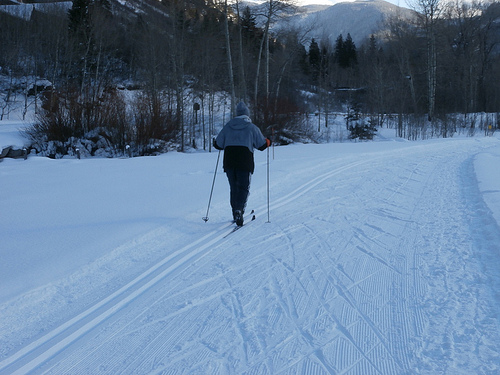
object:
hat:
[235, 100, 250, 116]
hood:
[228, 115, 252, 130]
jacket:
[213, 114, 272, 174]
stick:
[266, 146, 271, 223]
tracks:
[0, 135, 499, 375]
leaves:
[333, 30, 360, 70]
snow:
[0, 71, 500, 375]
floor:
[0, 136, 500, 375]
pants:
[225, 171, 252, 216]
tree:
[0, 0, 190, 160]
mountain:
[212, 0, 433, 62]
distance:
[0, 0, 500, 68]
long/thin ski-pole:
[263, 145, 272, 223]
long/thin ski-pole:
[202, 148, 223, 223]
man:
[212, 101, 272, 228]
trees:
[168, 0, 322, 148]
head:
[236, 99, 250, 118]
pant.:
[225, 168, 253, 213]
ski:
[221, 214, 255, 240]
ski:
[216, 208, 255, 234]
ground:
[3, 136, 500, 375]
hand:
[265, 135, 272, 147]